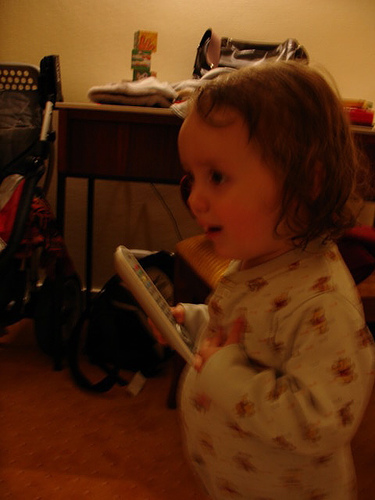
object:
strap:
[191, 27, 309, 81]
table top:
[49, 100, 374, 136]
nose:
[188, 169, 210, 218]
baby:
[147, 59, 375, 500]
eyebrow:
[199, 155, 227, 166]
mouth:
[203, 222, 223, 239]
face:
[178, 118, 273, 258]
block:
[133, 29, 158, 53]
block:
[131, 49, 153, 72]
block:
[133, 66, 151, 82]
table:
[50, 100, 374, 294]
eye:
[208, 168, 225, 186]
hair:
[193, 55, 356, 258]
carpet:
[11, 407, 168, 486]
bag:
[68, 249, 190, 409]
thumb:
[226, 313, 245, 345]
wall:
[0, 0, 375, 102]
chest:
[193, 272, 273, 409]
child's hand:
[191, 311, 247, 375]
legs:
[84, 178, 95, 291]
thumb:
[171, 302, 186, 323]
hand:
[147, 303, 186, 346]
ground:
[63, 427, 113, 472]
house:
[0, 0, 375, 500]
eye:
[182, 169, 195, 184]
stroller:
[0, 53, 90, 372]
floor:
[0, 314, 375, 500]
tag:
[126, 371, 147, 396]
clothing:
[177, 230, 374, 500]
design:
[308, 276, 331, 298]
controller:
[112, 243, 198, 367]